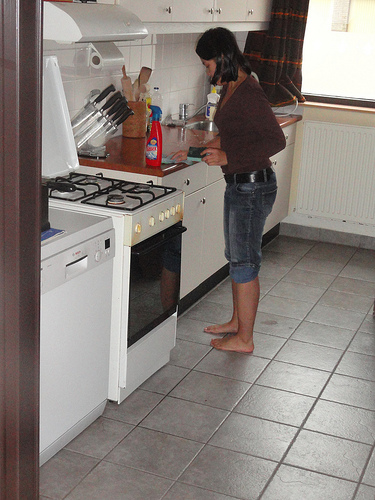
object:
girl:
[183, 25, 297, 370]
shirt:
[208, 75, 291, 179]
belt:
[219, 169, 275, 180]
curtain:
[253, 1, 318, 97]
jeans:
[213, 170, 281, 288]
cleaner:
[140, 101, 167, 173]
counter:
[76, 104, 309, 175]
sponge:
[186, 142, 210, 164]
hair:
[194, 26, 257, 91]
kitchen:
[0, 0, 375, 500]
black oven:
[131, 247, 178, 336]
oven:
[79, 178, 187, 407]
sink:
[185, 113, 222, 135]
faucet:
[169, 91, 219, 125]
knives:
[69, 82, 137, 150]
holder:
[68, 109, 120, 160]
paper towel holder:
[82, 40, 129, 75]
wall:
[43, 1, 289, 151]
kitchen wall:
[43, 26, 199, 141]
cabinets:
[113, 98, 302, 319]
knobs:
[165, 78, 294, 168]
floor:
[83, 277, 372, 499]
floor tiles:
[103, 263, 375, 498]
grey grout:
[62, 235, 374, 498]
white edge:
[177, 233, 223, 282]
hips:
[220, 169, 281, 186]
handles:
[94, 85, 116, 104]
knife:
[69, 80, 129, 154]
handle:
[99, 95, 123, 112]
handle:
[116, 112, 134, 122]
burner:
[82, 188, 148, 213]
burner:
[121, 180, 176, 201]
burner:
[44, 179, 101, 202]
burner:
[59, 158, 123, 185]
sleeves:
[240, 76, 284, 166]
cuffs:
[224, 258, 264, 285]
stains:
[131, 206, 187, 244]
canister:
[117, 97, 151, 140]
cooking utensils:
[114, 62, 154, 98]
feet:
[210, 332, 256, 358]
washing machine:
[37, 200, 121, 471]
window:
[294, 3, 373, 110]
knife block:
[70, 119, 112, 163]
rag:
[161, 148, 196, 166]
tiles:
[276, 220, 374, 255]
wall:
[281, 1, 373, 247]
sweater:
[216, 76, 291, 177]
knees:
[225, 255, 265, 286]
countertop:
[75, 107, 305, 179]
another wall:
[302, 0, 375, 102]